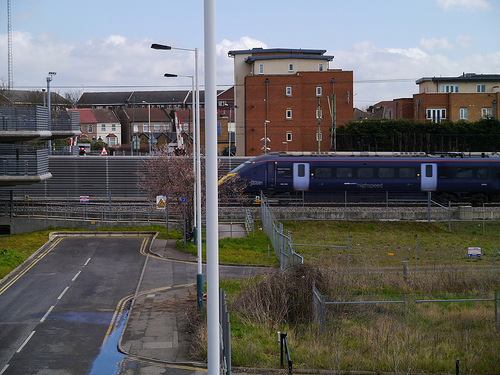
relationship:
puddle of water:
[88, 307, 133, 374] [97, 355, 114, 373]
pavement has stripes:
[5, 232, 147, 374] [78, 252, 95, 269]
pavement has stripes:
[5, 232, 147, 374] [66, 267, 88, 284]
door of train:
[292, 159, 313, 199] [204, 142, 486, 216]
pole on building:
[263, 74, 270, 152] [228, 47, 355, 156]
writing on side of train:
[344, 181, 384, 191] [218, 154, 497, 204]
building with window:
[201, 42, 394, 223] [302, 65, 334, 105]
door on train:
[293, 161, 310, 191] [221, 123, 449, 208]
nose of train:
[200, 163, 252, 205] [204, 141, 474, 205]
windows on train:
[259, 129, 452, 214] [216, 148, 484, 203]